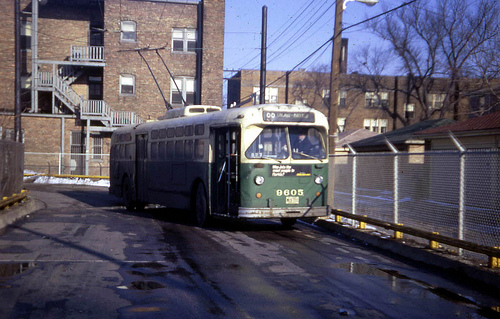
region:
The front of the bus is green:
[127, 103, 356, 248]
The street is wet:
[144, 210, 432, 293]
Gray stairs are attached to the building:
[24, 20, 212, 195]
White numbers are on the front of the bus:
[263, 159, 355, 231]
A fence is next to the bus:
[325, 133, 491, 231]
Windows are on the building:
[99, 5, 294, 140]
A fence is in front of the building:
[27, 115, 115, 211]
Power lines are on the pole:
[252, 13, 449, 153]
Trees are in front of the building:
[355, 14, 490, 154]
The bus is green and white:
[200, 94, 375, 283]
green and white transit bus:
[104, 98, 335, 230]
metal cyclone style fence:
[321, 125, 498, 267]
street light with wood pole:
[324, 0, 384, 215]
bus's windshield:
[242, 120, 332, 165]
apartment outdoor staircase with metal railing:
[15, 39, 152, 136]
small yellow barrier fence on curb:
[327, 209, 498, 293]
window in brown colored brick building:
[111, 13, 146, 47]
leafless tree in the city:
[340, 2, 499, 132]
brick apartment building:
[225, 65, 481, 185]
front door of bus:
[199, 117, 245, 223]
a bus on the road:
[60, 27, 483, 316]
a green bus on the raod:
[57, 46, 392, 282]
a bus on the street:
[129, 58, 389, 290]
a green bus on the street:
[61, 57, 362, 309]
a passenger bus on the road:
[71, 62, 369, 258]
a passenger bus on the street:
[86, 63, 400, 244]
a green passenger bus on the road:
[94, 86, 357, 298]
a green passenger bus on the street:
[97, 70, 443, 307]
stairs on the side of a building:
[12, 8, 240, 182]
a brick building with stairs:
[8, 9, 211, 204]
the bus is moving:
[83, 75, 354, 249]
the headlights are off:
[229, 160, 339, 197]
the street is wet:
[199, 246, 438, 316]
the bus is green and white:
[88, 81, 336, 240]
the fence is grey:
[331, 142, 498, 246]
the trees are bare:
[352, 15, 487, 111]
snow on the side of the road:
[15, 165, 106, 191]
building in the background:
[13, 8, 245, 111]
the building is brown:
[95, 0, 214, 99]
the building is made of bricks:
[102, 8, 217, 93]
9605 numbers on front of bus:
[275, 188, 305, 197]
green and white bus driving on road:
[108, 105, 330, 228]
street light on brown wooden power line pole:
[328, 0, 377, 208]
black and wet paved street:
[1, 182, 498, 317]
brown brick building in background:
[1, 0, 225, 179]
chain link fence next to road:
[325, 130, 497, 266]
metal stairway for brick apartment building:
[33, 43, 145, 124]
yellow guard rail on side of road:
[328, 208, 498, 269]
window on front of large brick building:
[171, 75, 196, 106]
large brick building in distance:
[227, 68, 499, 140]